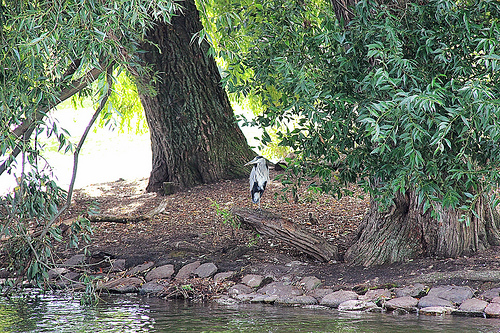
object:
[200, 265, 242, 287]
rock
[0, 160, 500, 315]
ground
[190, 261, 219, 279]
rock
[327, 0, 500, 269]
tree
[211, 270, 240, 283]
rock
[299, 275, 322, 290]
rock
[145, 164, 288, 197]
stem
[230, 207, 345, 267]
log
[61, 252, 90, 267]
rocks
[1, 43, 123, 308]
overhanging branch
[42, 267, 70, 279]
rocks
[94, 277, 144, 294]
rock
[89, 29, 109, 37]
leaves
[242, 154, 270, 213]
bird standing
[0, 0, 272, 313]
tree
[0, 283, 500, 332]
water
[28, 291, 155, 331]
sunlight reflecting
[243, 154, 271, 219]
bird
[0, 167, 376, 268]
hill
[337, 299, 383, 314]
rock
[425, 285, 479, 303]
rock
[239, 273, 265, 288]
rock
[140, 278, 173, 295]
rock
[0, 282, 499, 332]
pond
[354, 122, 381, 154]
part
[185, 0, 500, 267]
bush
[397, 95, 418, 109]
leaves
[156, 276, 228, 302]
pile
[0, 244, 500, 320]
rocky shore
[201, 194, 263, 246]
plant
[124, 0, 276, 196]
tree trunk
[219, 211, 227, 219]
leaves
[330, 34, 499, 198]
vegetation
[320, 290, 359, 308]
rock